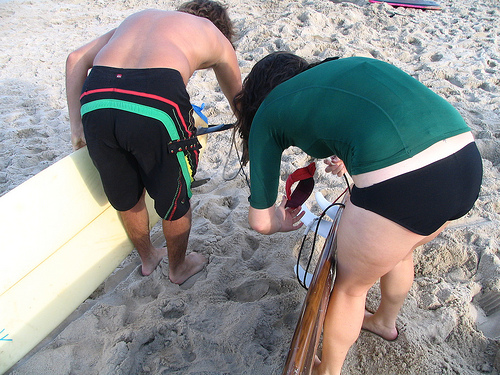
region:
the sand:
[170, 296, 247, 363]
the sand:
[167, 259, 242, 341]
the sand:
[143, 274, 259, 323]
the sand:
[177, 285, 260, 339]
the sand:
[122, 253, 241, 368]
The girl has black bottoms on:
[319, 160, 498, 259]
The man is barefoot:
[72, 231, 210, 370]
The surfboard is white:
[6, 166, 147, 323]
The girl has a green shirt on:
[242, 62, 473, 201]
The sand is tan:
[206, 200, 351, 352]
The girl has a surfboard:
[249, 237, 465, 337]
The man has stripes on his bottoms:
[73, 87, 266, 271]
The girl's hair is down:
[219, 67, 407, 234]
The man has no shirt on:
[63, 13, 360, 185]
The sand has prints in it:
[141, 238, 347, 370]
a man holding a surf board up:
[1, 19, 244, 304]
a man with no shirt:
[39, 10, 226, 140]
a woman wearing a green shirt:
[172, 5, 472, 239]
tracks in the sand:
[149, 276, 264, 373]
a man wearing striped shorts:
[94, 48, 193, 268]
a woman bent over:
[211, 42, 424, 289]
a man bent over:
[19, 20, 226, 278]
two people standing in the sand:
[52, 21, 457, 286]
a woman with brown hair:
[205, 31, 350, 174]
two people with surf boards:
[1, 32, 438, 327]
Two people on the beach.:
[49, 0, 469, 347]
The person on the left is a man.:
[59, 0, 238, 285]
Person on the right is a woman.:
[226, 43, 453, 374]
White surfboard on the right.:
[4, 98, 215, 373]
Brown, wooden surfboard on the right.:
[281, 163, 377, 368]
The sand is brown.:
[19, 10, 493, 362]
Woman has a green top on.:
[229, 46, 481, 230]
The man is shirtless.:
[47, 0, 266, 147]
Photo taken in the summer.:
[13, 6, 495, 370]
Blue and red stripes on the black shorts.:
[65, 55, 221, 232]